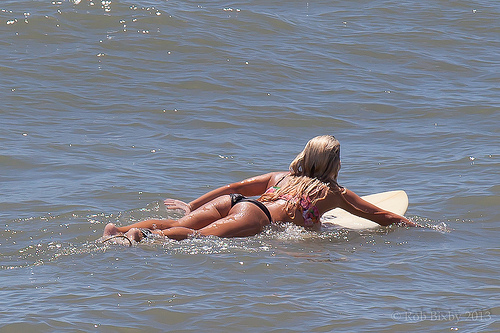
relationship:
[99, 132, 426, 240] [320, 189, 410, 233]
woman riding on surfboard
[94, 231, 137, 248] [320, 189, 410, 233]
rope attached to surfboard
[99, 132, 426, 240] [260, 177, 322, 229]
woman wearing shirt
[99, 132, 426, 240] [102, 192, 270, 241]
woman has legs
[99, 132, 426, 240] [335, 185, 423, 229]
woman has right arm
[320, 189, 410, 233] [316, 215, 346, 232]
surfboard has shadow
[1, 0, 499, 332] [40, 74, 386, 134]
water with small waves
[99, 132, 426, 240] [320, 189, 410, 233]
woman lying on surfboard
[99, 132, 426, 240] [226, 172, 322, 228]
woman wearing bikini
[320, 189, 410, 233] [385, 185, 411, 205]
surfboard has tip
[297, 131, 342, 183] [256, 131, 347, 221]
head has hair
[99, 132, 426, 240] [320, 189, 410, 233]
woman floating on surfboard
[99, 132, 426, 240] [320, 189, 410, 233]
woman on top of surfboard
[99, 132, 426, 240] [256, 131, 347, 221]
woman has hair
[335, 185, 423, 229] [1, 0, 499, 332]
arm submerged in water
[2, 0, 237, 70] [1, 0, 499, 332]
shining sun on water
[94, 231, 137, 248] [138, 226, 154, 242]
cord attached to ankle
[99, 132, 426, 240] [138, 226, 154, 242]
woman has ankle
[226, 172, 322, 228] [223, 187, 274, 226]
bikini has bottom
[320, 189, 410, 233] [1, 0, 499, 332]
surfboard floating on water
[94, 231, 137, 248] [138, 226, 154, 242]
tie around an ankle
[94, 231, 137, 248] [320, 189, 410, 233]
tie attached to surfboard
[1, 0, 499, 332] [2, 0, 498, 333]
ocean has waves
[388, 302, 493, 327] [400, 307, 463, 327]
watermark for rob bixby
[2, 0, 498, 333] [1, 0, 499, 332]
waves in water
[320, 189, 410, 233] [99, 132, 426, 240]
surfboard under woman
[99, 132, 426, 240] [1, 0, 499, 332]
woman riding on water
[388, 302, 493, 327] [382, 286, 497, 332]
watermark in corner